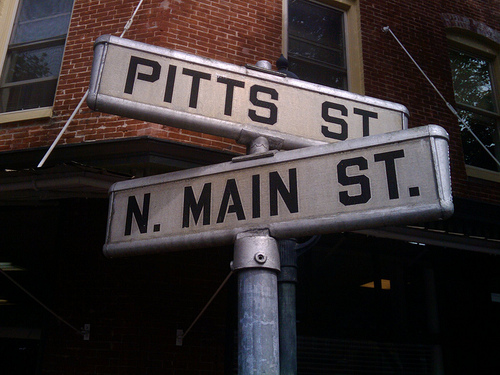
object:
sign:
[101, 123, 457, 258]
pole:
[233, 228, 282, 374]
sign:
[87, 34, 409, 155]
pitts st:
[123, 55, 378, 141]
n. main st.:
[123, 150, 422, 237]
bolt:
[255, 253, 267, 264]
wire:
[382, 24, 499, 168]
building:
[0, 0, 291, 160]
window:
[282, 1, 349, 94]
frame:
[280, 1, 365, 98]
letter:
[125, 194, 151, 237]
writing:
[124, 150, 422, 236]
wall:
[0, 0, 167, 151]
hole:
[254, 252, 266, 264]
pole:
[246, 135, 271, 157]